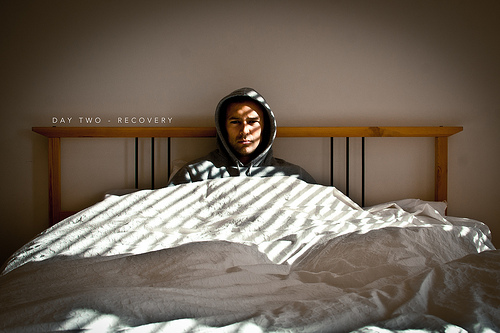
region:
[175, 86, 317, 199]
man in bed under covers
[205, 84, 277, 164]
gray hood on man's head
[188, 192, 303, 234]
shadow stripes on bedding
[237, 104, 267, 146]
shadows on man's face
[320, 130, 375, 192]
three poles on headboard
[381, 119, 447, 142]
wood on top of headboard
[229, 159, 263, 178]
strings on man's hoodie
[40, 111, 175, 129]
words above wood headboard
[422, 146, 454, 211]
wood pole attached to bed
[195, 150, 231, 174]
shadow on man's shoulder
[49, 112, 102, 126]
the words "day two" are displayed.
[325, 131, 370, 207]
three black posts on the headboard.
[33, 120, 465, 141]
the headboard is made of wood.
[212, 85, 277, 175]
a man sits in a bed.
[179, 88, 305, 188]
a man wears a gray hoodie.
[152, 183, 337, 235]
a reflection of stripes shows through the window on a white comforter.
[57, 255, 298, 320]
a white comforter.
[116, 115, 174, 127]
the word "recovery" is displayed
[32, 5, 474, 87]
the wall is tan and shaded.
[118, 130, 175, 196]
three posts casts a shadow.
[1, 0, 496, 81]
A taupe grey colored wall.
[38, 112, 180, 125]
White writing on the wall.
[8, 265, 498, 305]
A grey bed comforter.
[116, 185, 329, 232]
Sunlight shining through blinds.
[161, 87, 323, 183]
A serious man in bed.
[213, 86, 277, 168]
A man wearing a hood.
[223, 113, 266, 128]
The man's furrowed brows.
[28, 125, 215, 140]
The wooden headboard of bed.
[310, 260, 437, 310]
Wrinkled on the comforter.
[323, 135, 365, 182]
Three black thin rods.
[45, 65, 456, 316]
man in center of bed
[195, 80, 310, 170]
man with hood over head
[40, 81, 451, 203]
man sitting up against headboard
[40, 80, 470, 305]
light falling in slanted stripes across blanket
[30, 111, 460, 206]
metal rods in wooden frame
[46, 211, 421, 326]
parts of bedding in shade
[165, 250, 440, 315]
fabric folds on bedding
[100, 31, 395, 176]
grey walls in bedroom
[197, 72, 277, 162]
man with serious expression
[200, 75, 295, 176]
eyes forward and lips closed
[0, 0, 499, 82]
The dark walls of the room.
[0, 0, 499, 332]
A man sitting up in bed.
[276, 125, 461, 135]
The top of the wooden head board.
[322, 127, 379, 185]
The black spokes of the headboard.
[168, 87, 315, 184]
The man in grey.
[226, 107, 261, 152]
The man's troubled expression.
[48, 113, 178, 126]
The writing on the wall.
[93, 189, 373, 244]
The reflection of sunlight.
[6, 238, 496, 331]
The white bed covering.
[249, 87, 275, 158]
Sunlight on the man's face.